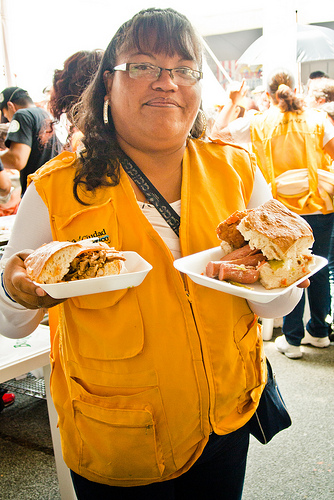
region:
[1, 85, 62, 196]
man wearing a black t shirt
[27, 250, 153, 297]
sandwich inside a white Styrofoam container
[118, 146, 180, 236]
black strap across chest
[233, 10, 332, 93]
a white umbrella is open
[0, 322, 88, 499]
white table to the left of woman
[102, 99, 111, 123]
woman wearing earring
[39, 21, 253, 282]
A woman with glasses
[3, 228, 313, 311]
Plates in the hands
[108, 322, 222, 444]
A yellow jacket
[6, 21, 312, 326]
People standing in the room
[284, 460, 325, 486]
Concrete floor in the photo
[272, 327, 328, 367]
White shoes in the photo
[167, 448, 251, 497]
Black pants in the photo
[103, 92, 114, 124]
Earring on the ear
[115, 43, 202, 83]
woman wearing glasses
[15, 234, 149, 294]
woman holding a plate of food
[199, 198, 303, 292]
sandwich on a tray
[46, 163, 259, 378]
woman wearing a yellow jacket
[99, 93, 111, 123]
woman with earrings in her ear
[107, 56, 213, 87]
woman wearing glasses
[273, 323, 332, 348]
person wearing white shoes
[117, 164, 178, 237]
women with a black strap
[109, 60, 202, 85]
Glasses on a woman's face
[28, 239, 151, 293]
Sandwich in a woman's hand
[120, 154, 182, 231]
Strap across a woman's neck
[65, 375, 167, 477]
Front pocket on a woman's coat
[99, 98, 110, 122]
Earring in woman's ear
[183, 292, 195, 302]
Zipper clasp on a coat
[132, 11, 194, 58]
Brown bangs on a woman's head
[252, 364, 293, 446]
Black bag hanging at woman's waist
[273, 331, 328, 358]
White shoes on a woman's feet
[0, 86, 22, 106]
Black hat on a man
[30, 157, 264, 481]
the vest is yellow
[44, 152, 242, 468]
the vest is yellow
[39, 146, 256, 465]
the vest is yellow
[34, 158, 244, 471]
the vest is yellow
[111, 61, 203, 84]
A pair of black glasses on a woman.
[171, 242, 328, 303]
A white rectangle plate with higher piled food.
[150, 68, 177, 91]
Nose on a dark skinned woman's face.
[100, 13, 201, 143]
person has a head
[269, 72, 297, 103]
person has a head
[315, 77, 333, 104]
person has a head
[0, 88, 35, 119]
person has a head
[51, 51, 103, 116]
person has a head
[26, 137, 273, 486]
person has on a shirt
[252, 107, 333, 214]
person has on a shirt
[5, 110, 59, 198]
person has on a shirt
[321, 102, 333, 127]
person has on a shirt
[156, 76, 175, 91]
nose on the woman's face